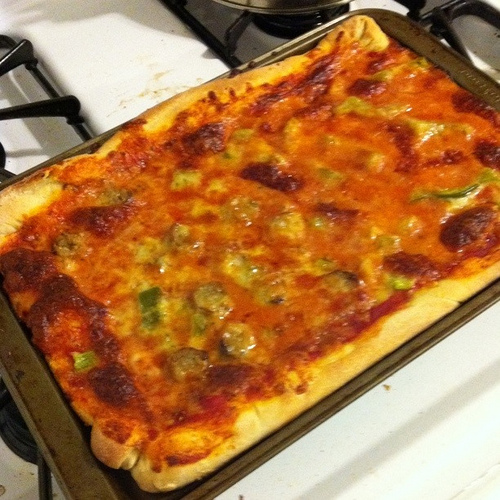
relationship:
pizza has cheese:
[0, 19, 500, 494] [4, 45, 499, 461]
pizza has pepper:
[0, 19, 500, 494] [135, 287, 169, 334]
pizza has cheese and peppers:
[0, 19, 500, 494] [0, 44, 500, 436]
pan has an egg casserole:
[0, 3, 495, 498] [0, 19, 500, 494]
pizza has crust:
[0, 19, 500, 494] [0, 14, 500, 492]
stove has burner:
[0, 1, 497, 498] [0, 26, 97, 191]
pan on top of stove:
[0, 3, 495, 498] [0, 1, 497, 498]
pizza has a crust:
[0, 19, 500, 494] [0, 14, 500, 492]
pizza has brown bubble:
[0, 19, 500, 494] [439, 206, 494, 254]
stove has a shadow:
[0, 1, 497, 498] [16, 0, 211, 62]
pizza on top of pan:
[0, 19, 500, 494] [0, 3, 495, 498]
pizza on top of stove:
[0, 19, 500, 494] [0, 1, 497, 498]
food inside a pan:
[0, 19, 500, 494] [0, 3, 495, 498]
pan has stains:
[0, 3, 495, 498] [382, 15, 453, 67]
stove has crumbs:
[0, 1, 497, 498] [114, 68, 206, 111]